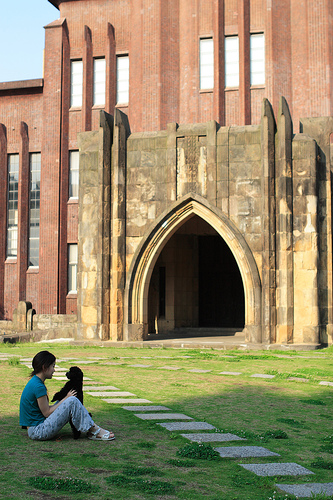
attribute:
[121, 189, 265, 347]
arch way — large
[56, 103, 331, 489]
structure —   stone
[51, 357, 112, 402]
dog — black 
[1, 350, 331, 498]
tiles — stone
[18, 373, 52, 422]
shirt — blue 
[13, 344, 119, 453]
girl — sitting 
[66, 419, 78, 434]
legs — hind,  dog's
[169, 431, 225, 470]
plant — very small, green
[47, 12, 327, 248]
building — tall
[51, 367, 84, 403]
dog — black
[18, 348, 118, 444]
lady —  light skinned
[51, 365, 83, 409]
dog — black 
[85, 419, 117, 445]
sandals — white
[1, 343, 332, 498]
yard — grassy 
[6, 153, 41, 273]
windows —  some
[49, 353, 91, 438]
dog — black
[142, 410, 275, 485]
footstep —   stone, for foot 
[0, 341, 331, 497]
grass —  area , green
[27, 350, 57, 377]
hair — dark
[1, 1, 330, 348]
wall — brown 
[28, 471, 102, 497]
weeds —  Some ,  overgrown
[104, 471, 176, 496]
weeds —  overgrown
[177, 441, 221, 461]
weeds —  overgrown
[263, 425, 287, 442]
weeds —  overgrown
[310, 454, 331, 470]
weeds —  overgrown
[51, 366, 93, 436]
dog — black, fuzzy